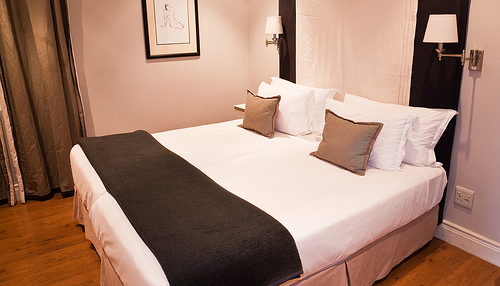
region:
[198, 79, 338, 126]
pillows on a bed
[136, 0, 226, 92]
a picture in a room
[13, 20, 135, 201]
curtains in a room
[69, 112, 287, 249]
a bed in a room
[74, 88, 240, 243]
a blanket in a room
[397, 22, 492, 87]
a light in a room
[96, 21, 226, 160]
a picture near a bed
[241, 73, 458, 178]
Six pillows on a white bed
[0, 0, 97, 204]
Brown drapes cascading to the floor.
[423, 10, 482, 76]
Light fixture on a wall.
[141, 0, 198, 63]
Painting hanging on a wall.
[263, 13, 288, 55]
Light fixture on a wall.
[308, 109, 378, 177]
A brown pillow on a bed.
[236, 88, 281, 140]
A brown pillow on the bed.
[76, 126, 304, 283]
A black blanket at the foot of a bed.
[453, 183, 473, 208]
Electrical outlet on the wall.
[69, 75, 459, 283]
A white bed with six pillows.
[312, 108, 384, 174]
a square brown pillow on a bed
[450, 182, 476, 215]
an outlet on the wall beside a bed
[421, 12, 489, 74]
a lamp attached to a wall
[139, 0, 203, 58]
a framed picture on a wall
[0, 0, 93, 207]
a brown curtain in a window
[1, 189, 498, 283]
a hardwood floor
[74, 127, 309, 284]
a blanket folded across the foot of a bed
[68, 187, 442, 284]
a light brown bed skirt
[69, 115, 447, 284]
a white sheet on a bed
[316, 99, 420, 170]
a white pillow on a bed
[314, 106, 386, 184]
a brown pillow on the bed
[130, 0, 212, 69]
a picture on the wall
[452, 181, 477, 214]
socket on the wall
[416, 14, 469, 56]
a lampstand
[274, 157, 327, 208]
white sheet on the bed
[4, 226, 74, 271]
the floor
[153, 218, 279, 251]
a black towel on the bed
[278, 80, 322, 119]
white pillows on the bed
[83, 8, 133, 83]
the wall of the room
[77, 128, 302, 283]
black blanket on bed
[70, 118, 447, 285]
the sheet is white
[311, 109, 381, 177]
the pillow is brown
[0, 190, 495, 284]
floor made of wood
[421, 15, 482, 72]
lamp on the wall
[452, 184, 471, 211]
a white electrical socket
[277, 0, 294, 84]
black trim on wall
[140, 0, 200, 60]
picture on the wall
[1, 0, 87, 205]
the curtain is green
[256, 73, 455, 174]
there are four white pillows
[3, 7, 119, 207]
The brown curtain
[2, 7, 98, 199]
A brown curtain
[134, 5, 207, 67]
The picture on the wall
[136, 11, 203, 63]
A picture on the wall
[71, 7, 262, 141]
The wall to the left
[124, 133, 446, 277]
this is a bed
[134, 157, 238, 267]
the blanket is black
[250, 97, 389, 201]
the pillows are small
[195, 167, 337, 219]
the sheets are white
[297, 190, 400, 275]
this is a mattress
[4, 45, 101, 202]
the curtain is light brown